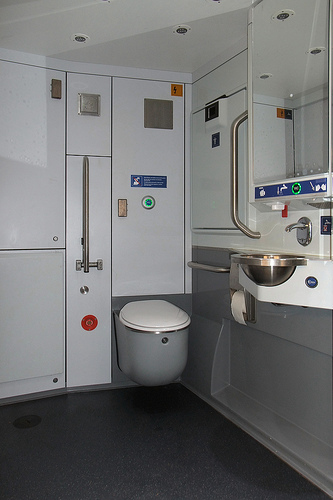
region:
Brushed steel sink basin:
[230, 249, 310, 287]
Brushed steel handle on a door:
[228, 107, 262, 239]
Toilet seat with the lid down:
[118, 298, 191, 331]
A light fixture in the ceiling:
[172, 24, 191, 36]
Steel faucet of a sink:
[285, 216, 312, 245]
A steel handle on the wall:
[186, 259, 229, 274]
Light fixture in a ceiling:
[71, 32, 89, 44]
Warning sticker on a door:
[131, 173, 169, 187]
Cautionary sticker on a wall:
[171, 83, 184, 96]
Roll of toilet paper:
[228, 288, 250, 326]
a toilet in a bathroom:
[108, 298, 191, 387]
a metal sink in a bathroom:
[228, 253, 310, 290]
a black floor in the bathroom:
[2, 379, 332, 498]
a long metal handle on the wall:
[229, 108, 262, 241]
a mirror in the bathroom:
[247, 2, 332, 185]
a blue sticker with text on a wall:
[129, 174, 168, 188]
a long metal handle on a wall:
[74, 152, 104, 275]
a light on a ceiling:
[70, 33, 91, 46]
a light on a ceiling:
[171, 23, 192, 36]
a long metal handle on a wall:
[181, 258, 232, 274]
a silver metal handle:
[213, 105, 264, 253]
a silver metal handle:
[208, 93, 260, 255]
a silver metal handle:
[212, 109, 265, 253]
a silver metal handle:
[223, 99, 257, 251]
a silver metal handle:
[217, 96, 269, 252]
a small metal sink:
[228, 247, 312, 312]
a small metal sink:
[227, 230, 307, 310]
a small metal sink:
[221, 230, 318, 315]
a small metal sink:
[213, 238, 315, 305]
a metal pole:
[230, 172, 239, 200]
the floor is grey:
[86, 427, 152, 468]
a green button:
[142, 194, 157, 211]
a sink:
[238, 249, 276, 267]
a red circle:
[79, 314, 100, 331]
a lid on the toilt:
[142, 305, 168, 321]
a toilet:
[116, 302, 197, 392]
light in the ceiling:
[274, 2, 291, 26]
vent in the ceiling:
[173, 25, 189, 43]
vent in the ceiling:
[67, 28, 93, 48]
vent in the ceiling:
[254, 69, 270, 86]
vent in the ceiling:
[301, 41, 325, 62]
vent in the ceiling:
[269, 3, 294, 27]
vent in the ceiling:
[75, 31, 88, 49]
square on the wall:
[79, 95, 98, 115]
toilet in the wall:
[103, 280, 186, 379]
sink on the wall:
[226, 249, 294, 293]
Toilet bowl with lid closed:
[113, 300, 192, 385]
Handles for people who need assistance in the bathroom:
[83, 112, 260, 291]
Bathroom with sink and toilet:
[0, 8, 330, 497]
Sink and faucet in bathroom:
[230, 214, 313, 287]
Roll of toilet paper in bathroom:
[230, 290, 247, 326]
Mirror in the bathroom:
[284, 97, 331, 178]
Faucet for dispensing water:
[281, 215, 312, 247]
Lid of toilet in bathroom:
[117, 301, 189, 330]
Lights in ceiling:
[68, 10, 332, 80]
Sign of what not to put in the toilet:
[128, 173, 166, 189]